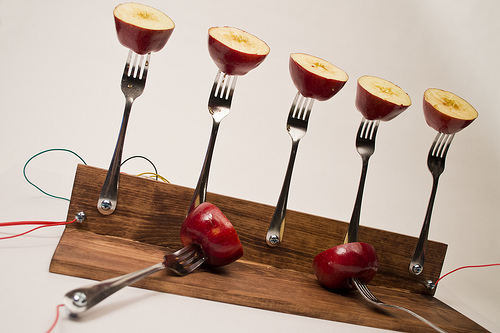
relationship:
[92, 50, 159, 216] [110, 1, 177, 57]
fork in apple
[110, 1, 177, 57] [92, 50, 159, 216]
apple on fork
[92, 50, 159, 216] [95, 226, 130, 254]
fork on wood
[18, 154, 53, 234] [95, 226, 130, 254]
wires on wood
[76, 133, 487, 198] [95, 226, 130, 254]
forks on wood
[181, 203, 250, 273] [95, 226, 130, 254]
apple on wood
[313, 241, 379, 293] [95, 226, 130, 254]
apple on wood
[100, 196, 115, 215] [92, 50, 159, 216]
tines on fork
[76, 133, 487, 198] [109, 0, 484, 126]
forks with red apples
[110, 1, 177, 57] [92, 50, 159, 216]
apple attached to fork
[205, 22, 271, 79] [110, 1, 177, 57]
half of a apple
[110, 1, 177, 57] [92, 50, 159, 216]
apple stuck on fork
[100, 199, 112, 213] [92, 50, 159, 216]
screw in fork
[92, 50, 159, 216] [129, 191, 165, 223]
fork attached to board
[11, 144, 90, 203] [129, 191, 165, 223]
wire attached to board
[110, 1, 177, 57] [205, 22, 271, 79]
apple cut in half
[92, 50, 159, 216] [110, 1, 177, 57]
fork with half apple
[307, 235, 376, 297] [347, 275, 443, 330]
apple attached to fork